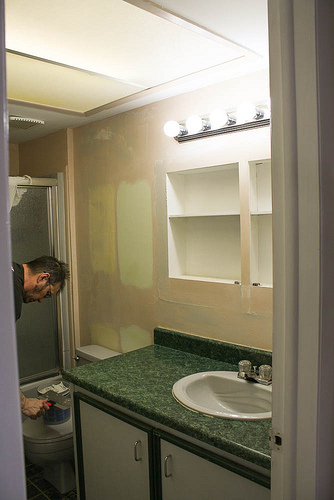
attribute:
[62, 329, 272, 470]
counter — green, granite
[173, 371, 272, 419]
sink — white, porcelain, round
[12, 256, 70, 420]
man — fixing, working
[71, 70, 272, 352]
wall — bare, faded, stained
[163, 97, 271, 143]
lights — on, silver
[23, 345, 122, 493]
toilet — white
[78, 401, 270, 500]
cupboard — white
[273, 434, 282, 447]
hole — small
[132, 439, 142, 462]
handle — silver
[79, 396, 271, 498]
cabinet — white, black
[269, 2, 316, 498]
door frame — white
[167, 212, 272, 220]
shelves — built in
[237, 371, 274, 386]
faucet — silver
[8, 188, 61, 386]
glass — clear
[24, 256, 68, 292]
hair — dark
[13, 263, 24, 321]
shirt — dark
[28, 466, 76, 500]
tile — dark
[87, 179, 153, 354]
paint — light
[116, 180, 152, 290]
paint — yellow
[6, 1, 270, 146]
ceiling — lit